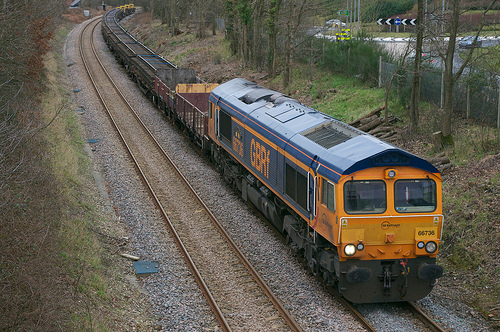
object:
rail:
[119, 136, 300, 332]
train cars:
[100, 7, 237, 139]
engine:
[167, 74, 447, 309]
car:
[458, 35, 483, 49]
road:
[363, 35, 497, 79]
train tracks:
[296, 16, 363, 38]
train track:
[74, 5, 461, 330]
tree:
[440, 8, 459, 146]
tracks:
[81, 28, 302, 332]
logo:
[246, 137, 271, 179]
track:
[268, 198, 445, 332]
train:
[202, 65, 452, 308]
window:
[342, 178, 387, 214]